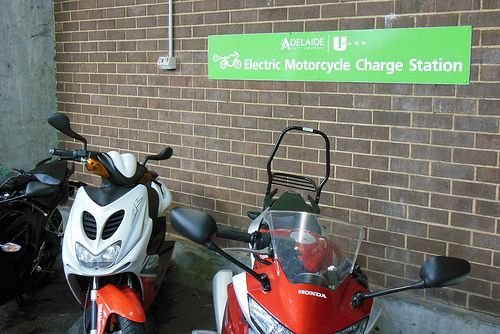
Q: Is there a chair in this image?
A: No, there are no chairs.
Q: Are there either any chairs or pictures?
A: No, there are no chairs or pictures.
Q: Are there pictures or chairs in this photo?
A: No, there are no chairs or pictures.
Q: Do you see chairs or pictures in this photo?
A: No, there are no chairs or pictures.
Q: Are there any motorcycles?
A: Yes, there is a motorcycle.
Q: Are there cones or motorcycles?
A: Yes, there is a motorcycle.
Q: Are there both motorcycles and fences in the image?
A: No, there is a motorcycle but no fences.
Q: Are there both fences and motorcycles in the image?
A: No, there is a motorcycle but no fences.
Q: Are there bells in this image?
A: No, there are no bells.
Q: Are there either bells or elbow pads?
A: No, there are no bells or elbow pads.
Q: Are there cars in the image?
A: No, there are no cars.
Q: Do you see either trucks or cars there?
A: No, there are no cars or trucks.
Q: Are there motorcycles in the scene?
A: Yes, there is a motorcycle.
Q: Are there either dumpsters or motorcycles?
A: Yes, there is a motorcycle.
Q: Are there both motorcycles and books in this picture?
A: No, there is a motorcycle but no books.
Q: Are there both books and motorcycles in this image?
A: No, there is a motorcycle but no books.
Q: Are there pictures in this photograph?
A: No, there are no pictures.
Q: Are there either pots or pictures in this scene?
A: No, there are no pictures or pots.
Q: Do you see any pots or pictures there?
A: No, there are no pictures or pots.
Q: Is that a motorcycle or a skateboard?
A: That is a motorcycle.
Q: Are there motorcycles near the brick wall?
A: Yes, there is a motorcycle near the wall.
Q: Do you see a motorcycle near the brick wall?
A: Yes, there is a motorcycle near the wall.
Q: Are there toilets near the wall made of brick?
A: No, there is a motorcycle near the wall.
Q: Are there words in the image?
A: Yes, there are words.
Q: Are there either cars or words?
A: Yes, there are words.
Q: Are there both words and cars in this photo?
A: No, there are words but no cars.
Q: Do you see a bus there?
A: No, there are no buses.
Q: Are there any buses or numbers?
A: No, there are no buses or numbers.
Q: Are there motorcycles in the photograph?
A: Yes, there is a motorcycle.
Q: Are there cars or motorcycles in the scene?
A: Yes, there is a motorcycle.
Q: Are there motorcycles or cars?
A: Yes, there is a motorcycle.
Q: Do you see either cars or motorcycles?
A: Yes, there is a motorcycle.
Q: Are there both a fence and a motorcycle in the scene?
A: No, there is a motorcycle but no fences.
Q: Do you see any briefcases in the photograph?
A: No, there are no briefcases.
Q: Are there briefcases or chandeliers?
A: No, there are no briefcases or chandeliers.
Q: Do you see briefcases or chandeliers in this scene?
A: No, there are no briefcases or chandeliers.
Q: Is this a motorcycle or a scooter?
A: This is a motorcycle.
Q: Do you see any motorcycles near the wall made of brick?
A: Yes, there is a motorcycle near the wall.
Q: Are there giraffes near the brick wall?
A: No, there is a motorcycle near the wall.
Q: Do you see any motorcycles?
A: Yes, there is a motorcycle.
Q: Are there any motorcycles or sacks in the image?
A: Yes, there is a motorcycle.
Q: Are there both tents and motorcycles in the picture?
A: No, there is a motorcycle but no tents.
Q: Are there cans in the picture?
A: No, there are no cans.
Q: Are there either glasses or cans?
A: No, there are no cans or glasses.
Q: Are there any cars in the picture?
A: No, there are no cars.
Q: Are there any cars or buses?
A: No, there are no cars or buses.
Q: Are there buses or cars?
A: No, there are no cars or buses.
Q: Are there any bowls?
A: No, there are no bowls.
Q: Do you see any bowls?
A: No, there are no bowls.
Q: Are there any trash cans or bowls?
A: No, there are no bowls or trash cans.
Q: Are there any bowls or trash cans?
A: No, there are no bowls or trash cans.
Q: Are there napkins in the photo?
A: No, there are no napkins.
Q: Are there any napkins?
A: No, there are no napkins.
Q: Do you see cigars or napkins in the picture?
A: No, there are no napkins or cigars.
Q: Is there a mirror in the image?
A: Yes, there is a mirror.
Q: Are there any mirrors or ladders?
A: Yes, there is a mirror.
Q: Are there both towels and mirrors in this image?
A: No, there is a mirror but no towels.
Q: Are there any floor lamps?
A: No, there are no floor lamps.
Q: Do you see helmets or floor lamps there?
A: No, there are no floor lamps or helmets.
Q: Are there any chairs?
A: No, there are no chairs.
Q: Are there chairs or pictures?
A: No, there are no chairs or pictures.